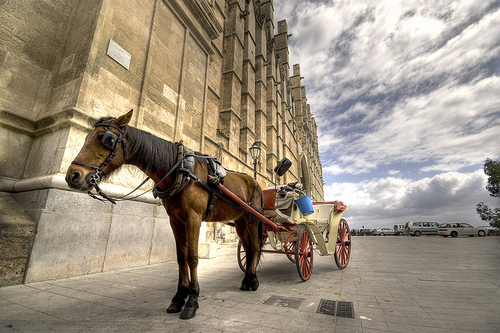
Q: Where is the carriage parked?
A: Next to the building.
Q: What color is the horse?
A: Brown.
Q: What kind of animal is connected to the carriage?
A: Horse.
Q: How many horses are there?
A: 1.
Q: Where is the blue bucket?
A: Hanging off the carriage.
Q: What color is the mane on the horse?
A: Black.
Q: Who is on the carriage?
A: Nobody.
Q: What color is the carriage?
A: Cream.